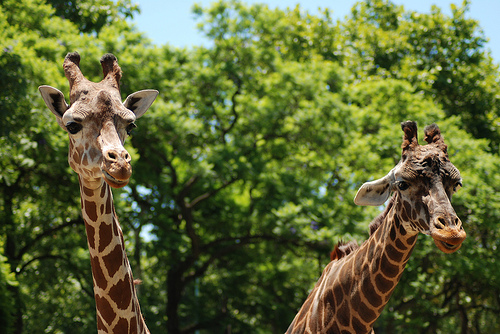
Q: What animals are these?
A: Giraffes.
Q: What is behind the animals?
A: Trees.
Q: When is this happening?
A: During the day time.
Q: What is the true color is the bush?
A: Green.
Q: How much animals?
A: 2.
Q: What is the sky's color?
A: Blue.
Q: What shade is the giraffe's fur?
A: Brown and white.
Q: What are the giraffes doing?
A: Looking at the camera.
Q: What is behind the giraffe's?
A: Trees.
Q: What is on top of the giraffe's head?
A: Horns.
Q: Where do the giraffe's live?
A: The zoo.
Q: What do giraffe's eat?
A: Leaves.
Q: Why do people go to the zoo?
A: To see the giraffes.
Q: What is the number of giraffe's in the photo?
A: Two.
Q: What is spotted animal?
A: Giraffe.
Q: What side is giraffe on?
A: Right.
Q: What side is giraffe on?
A: Left.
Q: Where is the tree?
A: In background.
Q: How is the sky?
A: Cloudless.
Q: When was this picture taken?
A: During the day.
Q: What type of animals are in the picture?
A: Giraffes.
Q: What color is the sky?
A: Blue.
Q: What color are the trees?
A: Green.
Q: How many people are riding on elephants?
A: Zero.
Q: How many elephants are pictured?
A: Zero.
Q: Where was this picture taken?
A: At the zoo.